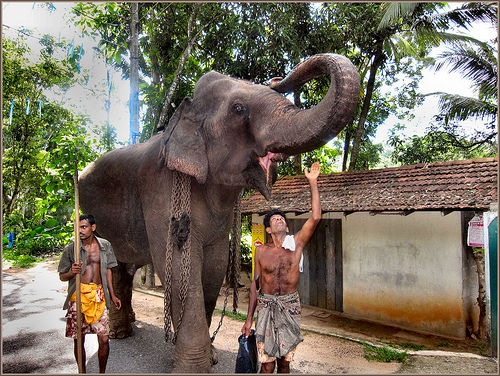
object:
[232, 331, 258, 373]
bag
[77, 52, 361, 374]
elephant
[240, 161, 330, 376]
man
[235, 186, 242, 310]
chains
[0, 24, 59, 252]
tree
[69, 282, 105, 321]
yellow material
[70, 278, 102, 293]
waist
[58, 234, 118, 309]
green shirt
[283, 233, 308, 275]
shirt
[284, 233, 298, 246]
shoulder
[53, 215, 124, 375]
man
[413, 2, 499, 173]
tree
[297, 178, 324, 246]
arm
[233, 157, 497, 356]
building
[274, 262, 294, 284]
shingles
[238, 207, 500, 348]
wall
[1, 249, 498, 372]
path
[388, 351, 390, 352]
weeds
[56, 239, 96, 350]
side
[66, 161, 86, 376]
pole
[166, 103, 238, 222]
neck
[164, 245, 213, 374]
leg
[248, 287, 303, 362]
shirt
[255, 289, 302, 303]
waist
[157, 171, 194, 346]
chain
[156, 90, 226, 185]
ear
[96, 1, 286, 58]
top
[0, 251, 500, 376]
ground